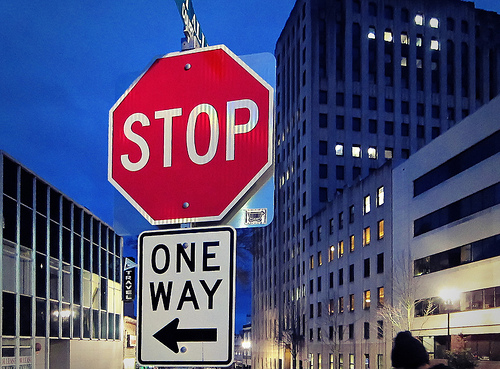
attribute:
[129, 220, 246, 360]
sign — black, white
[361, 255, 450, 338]
tree — bare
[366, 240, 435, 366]
tree — bare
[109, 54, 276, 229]
sign — red, white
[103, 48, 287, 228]
sign — red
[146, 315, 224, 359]
arrow — black